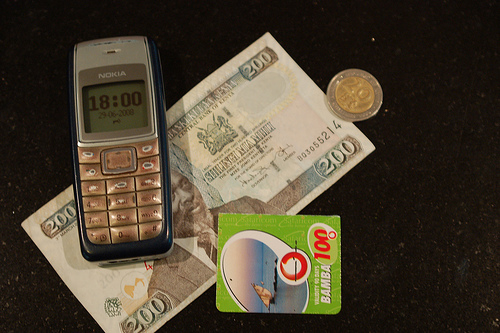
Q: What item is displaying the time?
A: The cell phone.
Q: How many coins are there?
A: 1.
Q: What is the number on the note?
A: 200.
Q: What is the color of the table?
A: Black.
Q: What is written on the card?
A: Bamba.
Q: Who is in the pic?
A: No one.